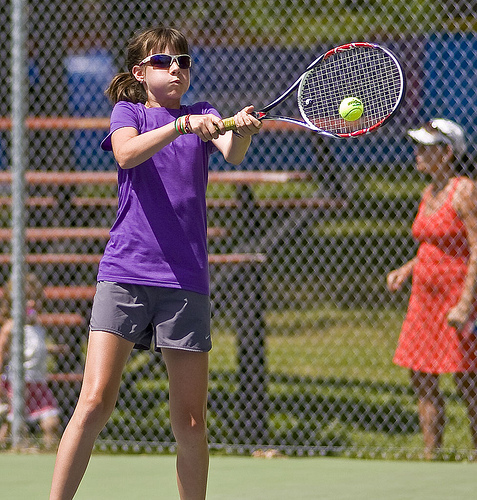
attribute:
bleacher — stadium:
[44, 110, 105, 284]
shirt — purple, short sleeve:
[86, 100, 225, 299]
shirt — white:
[1, 321, 50, 380]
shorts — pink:
[4, 380, 60, 422]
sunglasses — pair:
[136, 52, 196, 72]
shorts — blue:
[77, 275, 220, 352]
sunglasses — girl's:
[138, 51, 193, 70]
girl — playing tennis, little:
[42, 33, 260, 493]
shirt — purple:
[101, 95, 216, 289]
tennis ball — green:
[339, 98, 363, 117]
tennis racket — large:
[215, 43, 408, 140]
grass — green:
[339, 312, 368, 346]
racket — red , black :
[220, 40, 407, 140]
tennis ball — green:
[338, 94, 366, 122]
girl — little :
[108, 25, 242, 258]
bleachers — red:
[0, 70, 351, 432]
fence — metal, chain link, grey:
[4, 3, 472, 456]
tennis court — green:
[0, 450, 476, 498]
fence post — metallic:
[10, 5, 35, 452]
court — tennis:
[0, 451, 474, 497]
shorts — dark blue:
[91, 276, 210, 352]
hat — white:
[367, 94, 467, 152]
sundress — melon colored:
[391, 177, 475, 377]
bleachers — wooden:
[19, 101, 96, 284]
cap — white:
[407, 117, 466, 163]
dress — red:
[386, 170, 462, 374]